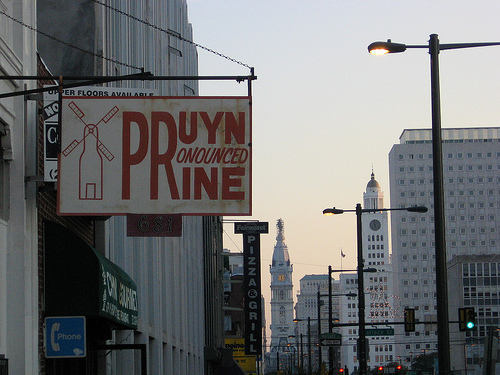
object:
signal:
[458, 307, 476, 331]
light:
[465, 322, 472, 329]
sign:
[41, 313, 88, 360]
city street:
[245, 54, 434, 369]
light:
[287, 344, 290, 346]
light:
[368, 40, 406, 55]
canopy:
[44, 229, 139, 333]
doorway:
[38, 309, 145, 374]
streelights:
[336, 363, 423, 373]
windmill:
[364, 163, 385, 195]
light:
[322, 208, 343, 216]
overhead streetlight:
[293, 318, 298, 322]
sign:
[320, 332, 342, 346]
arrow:
[321, 339, 341, 345]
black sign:
[233, 221, 270, 372]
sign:
[55, 94, 251, 216]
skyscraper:
[268, 218, 294, 365]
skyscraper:
[384, 124, 498, 369]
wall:
[163, 73, 285, 123]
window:
[277, 274, 285, 281]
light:
[467, 322, 475, 329]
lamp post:
[424, 36, 452, 374]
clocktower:
[356, 164, 394, 374]